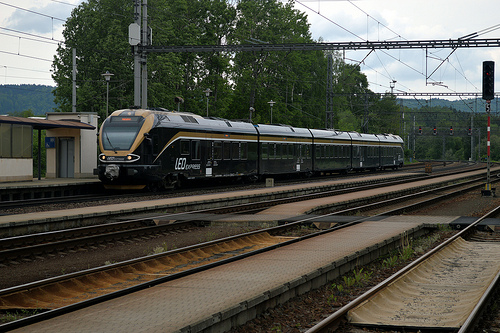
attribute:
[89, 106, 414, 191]
train — black, long, tan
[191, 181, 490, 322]
tracks — empty, metal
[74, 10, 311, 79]
leaves — green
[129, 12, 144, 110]
pole — metal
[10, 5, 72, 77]
lines — electrical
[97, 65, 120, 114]
lamp — off, grey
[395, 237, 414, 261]
grass — green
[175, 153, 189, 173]
word — white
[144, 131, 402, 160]
stripe — white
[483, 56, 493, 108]
light — black